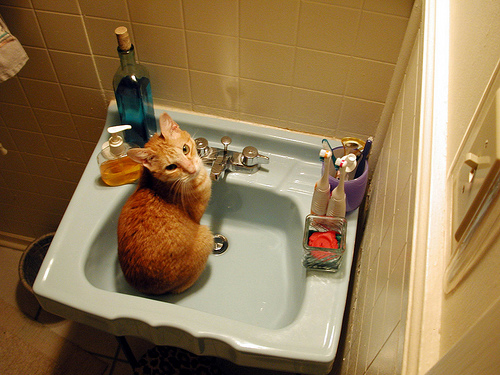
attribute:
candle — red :
[306, 228, 338, 265]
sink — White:
[43, 92, 345, 352]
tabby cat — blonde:
[126, 115, 211, 297]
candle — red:
[304, 217, 352, 276]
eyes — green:
[163, 141, 194, 174]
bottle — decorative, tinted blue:
[107, 25, 162, 145]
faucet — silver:
[186, 119, 261, 179]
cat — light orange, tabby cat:
[115, 112, 213, 299]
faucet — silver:
[188, 133, 270, 187]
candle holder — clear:
[301, 210, 348, 277]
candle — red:
[307, 230, 339, 257]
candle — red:
[307, 229, 339, 262]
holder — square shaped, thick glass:
[299, 212, 351, 279]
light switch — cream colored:
[451, 86, 499, 239]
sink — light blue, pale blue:
[29, 98, 365, 368]